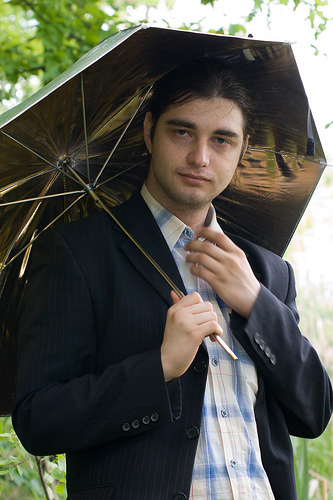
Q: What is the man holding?
A: An umbrella.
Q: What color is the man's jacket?
A: Blue.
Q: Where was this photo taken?
A: Near a tree.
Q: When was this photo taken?
A: During the daytime.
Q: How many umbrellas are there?
A: One.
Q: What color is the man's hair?
A: Black.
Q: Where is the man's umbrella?
A: On his shoulder.